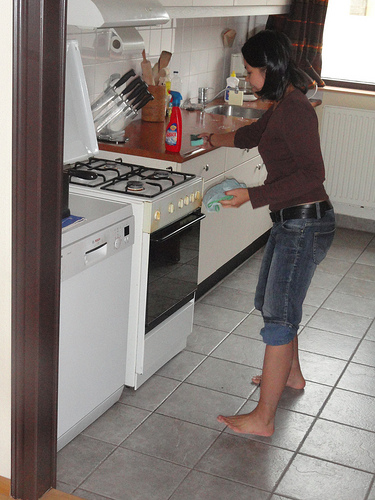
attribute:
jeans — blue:
[252, 199, 337, 345]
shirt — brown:
[233, 85, 330, 207]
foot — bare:
[214, 413, 276, 436]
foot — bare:
[250, 370, 306, 389]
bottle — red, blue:
[161, 87, 182, 153]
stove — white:
[62, 38, 206, 391]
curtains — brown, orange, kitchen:
[291, 8, 338, 93]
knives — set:
[88, 49, 160, 141]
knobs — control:
[145, 183, 226, 217]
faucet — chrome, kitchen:
[192, 81, 259, 112]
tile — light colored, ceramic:
[120, 425, 288, 497]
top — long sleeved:
[238, 97, 364, 212]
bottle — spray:
[158, 92, 200, 174]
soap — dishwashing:
[214, 62, 243, 110]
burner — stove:
[107, 167, 164, 200]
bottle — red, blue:
[167, 85, 200, 168]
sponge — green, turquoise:
[191, 174, 259, 215]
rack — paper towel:
[102, 30, 167, 60]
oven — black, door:
[76, 144, 238, 396]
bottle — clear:
[214, 69, 250, 113]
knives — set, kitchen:
[92, 63, 170, 135]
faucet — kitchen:
[183, 75, 234, 104]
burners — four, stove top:
[75, 152, 209, 227]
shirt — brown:
[231, 97, 359, 252]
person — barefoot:
[223, 18, 349, 395]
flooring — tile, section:
[122, 427, 162, 491]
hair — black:
[228, 31, 320, 124]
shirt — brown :
[226, 88, 335, 206]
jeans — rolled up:
[251, 197, 344, 342]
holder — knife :
[96, 91, 132, 133]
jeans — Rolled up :
[255, 203, 333, 342]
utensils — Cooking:
[96, 67, 166, 152]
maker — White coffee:
[225, 52, 247, 107]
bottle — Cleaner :
[163, 84, 189, 153]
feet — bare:
[223, 364, 308, 443]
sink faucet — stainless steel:
[186, 84, 239, 111]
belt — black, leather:
[270, 198, 331, 221]